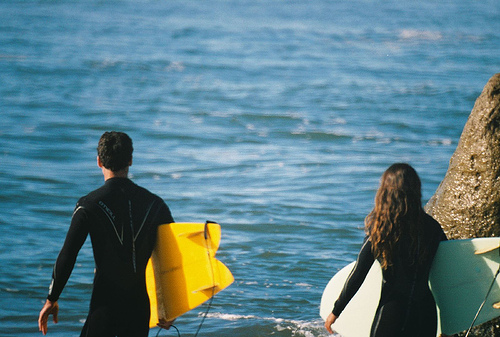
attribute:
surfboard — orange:
[142, 218, 242, 333]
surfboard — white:
[313, 231, 483, 333]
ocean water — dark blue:
[1, 2, 484, 333]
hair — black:
[83, 133, 143, 173]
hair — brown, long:
[328, 130, 438, 275]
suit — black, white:
[69, 158, 185, 286]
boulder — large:
[395, 38, 488, 204]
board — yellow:
[71, 174, 281, 321]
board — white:
[289, 238, 490, 317]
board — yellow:
[154, 159, 187, 322]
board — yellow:
[164, 210, 218, 303]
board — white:
[336, 194, 496, 315]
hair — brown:
[344, 150, 439, 288]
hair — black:
[104, 104, 134, 183]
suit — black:
[69, 180, 181, 300]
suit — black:
[333, 202, 453, 324]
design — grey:
[94, 191, 172, 278]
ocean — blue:
[146, 66, 272, 185]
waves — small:
[204, 104, 412, 264]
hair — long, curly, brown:
[373, 156, 438, 270]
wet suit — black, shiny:
[328, 175, 455, 335]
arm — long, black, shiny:
[324, 233, 378, 334]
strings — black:
[189, 216, 269, 262]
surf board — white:
[454, 247, 490, 306]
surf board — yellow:
[166, 211, 238, 303]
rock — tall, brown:
[447, 146, 487, 205]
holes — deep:
[457, 148, 488, 178]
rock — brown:
[418, 74, 499, 215]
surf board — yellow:
[128, 215, 237, 319]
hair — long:
[367, 154, 423, 234]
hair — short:
[78, 126, 144, 175]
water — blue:
[190, 45, 359, 174]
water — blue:
[182, 49, 312, 171]